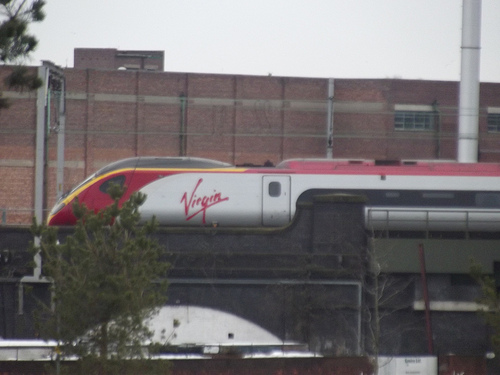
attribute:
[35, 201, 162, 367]
tree — small, green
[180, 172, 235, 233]
logo — red 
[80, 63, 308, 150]
brick building — red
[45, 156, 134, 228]
nose — red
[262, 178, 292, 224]
door — train's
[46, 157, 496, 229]
train — silver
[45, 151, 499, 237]
train engine — red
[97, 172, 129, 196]
window — train, cockpit